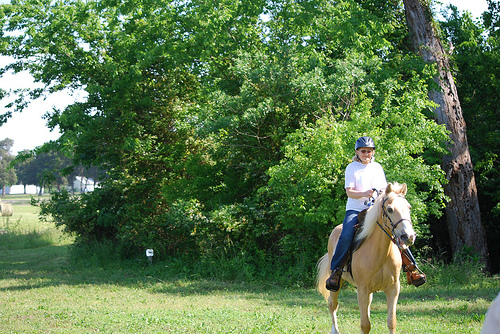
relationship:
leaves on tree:
[169, 162, 224, 218] [143, 87, 273, 259]